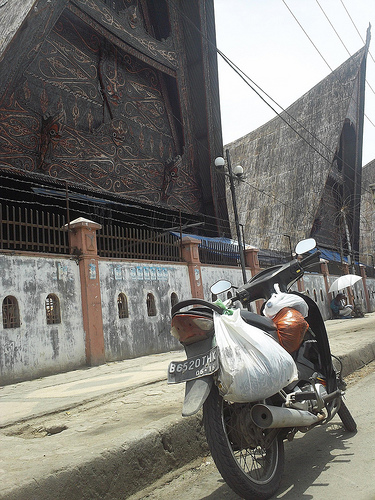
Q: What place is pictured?
A: It is a sidewalk.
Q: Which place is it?
A: It is a sidewalk.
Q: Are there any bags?
A: Yes, there is a bag.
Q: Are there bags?
A: Yes, there is a bag.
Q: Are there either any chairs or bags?
A: Yes, there is a bag.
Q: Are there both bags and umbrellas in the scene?
A: Yes, there are both a bag and an umbrella.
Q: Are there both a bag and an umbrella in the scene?
A: Yes, there are both a bag and an umbrella.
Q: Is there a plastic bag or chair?
A: Yes, there is a plastic bag.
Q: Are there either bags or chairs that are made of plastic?
A: Yes, the bag is made of plastic.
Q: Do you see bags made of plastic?
A: Yes, there is a bag that is made of plastic.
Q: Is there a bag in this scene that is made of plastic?
A: Yes, there is a bag that is made of plastic.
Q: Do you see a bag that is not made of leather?
A: Yes, there is a bag that is made of plastic.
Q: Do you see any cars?
A: No, there are no cars.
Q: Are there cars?
A: No, there are no cars.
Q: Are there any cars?
A: No, there are no cars.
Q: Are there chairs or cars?
A: No, there are no cars or chairs.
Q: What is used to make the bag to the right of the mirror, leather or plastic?
A: The bag is made of plastic.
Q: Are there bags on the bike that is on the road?
A: Yes, there is a bag on the bike.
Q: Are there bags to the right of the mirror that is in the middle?
A: Yes, there is a bag to the right of the mirror.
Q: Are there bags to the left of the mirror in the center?
A: No, the bag is to the right of the mirror.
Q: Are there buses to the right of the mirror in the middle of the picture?
A: No, there is a bag to the right of the mirror.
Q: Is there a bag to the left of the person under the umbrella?
A: Yes, there is a bag to the left of the person.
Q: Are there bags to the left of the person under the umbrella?
A: Yes, there is a bag to the left of the person.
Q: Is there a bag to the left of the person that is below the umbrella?
A: Yes, there is a bag to the left of the person.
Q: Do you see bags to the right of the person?
A: No, the bag is to the left of the person.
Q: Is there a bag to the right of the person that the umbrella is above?
A: No, the bag is to the left of the person.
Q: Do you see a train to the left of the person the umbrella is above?
A: No, there is a bag to the left of the person.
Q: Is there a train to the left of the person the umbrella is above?
A: No, there is a bag to the left of the person.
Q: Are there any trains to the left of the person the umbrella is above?
A: No, there is a bag to the left of the person.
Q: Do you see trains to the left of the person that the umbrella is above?
A: No, there is a bag to the left of the person.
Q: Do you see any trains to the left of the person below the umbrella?
A: No, there is a bag to the left of the person.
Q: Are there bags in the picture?
A: Yes, there is a bag.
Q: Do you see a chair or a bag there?
A: Yes, there is a bag.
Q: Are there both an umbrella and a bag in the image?
A: Yes, there are both a bag and an umbrella.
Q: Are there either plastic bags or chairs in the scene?
A: Yes, there is a plastic bag.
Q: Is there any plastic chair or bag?
A: Yes, there is a plastic bag.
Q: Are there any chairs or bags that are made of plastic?
A: Yes, the bag is made of plastic.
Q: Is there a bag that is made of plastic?
A: Yes, there is a bag that is made of plastic.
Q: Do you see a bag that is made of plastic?
A: Yes, there is a bag that is made of plastic.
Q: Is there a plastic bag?
A: Yes, there is a bag that is made of plastic.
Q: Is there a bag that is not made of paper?
A: Yes, there is a bag that is made of plastic.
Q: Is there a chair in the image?
A: No, there are no chairs.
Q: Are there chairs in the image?
A: No, there are no chairs.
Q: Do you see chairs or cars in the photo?
A: No, there are no chairs or cars.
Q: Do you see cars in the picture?
A: No, there are no cars.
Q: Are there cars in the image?
A: No, there are no cars.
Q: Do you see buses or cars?
A: No, there are no cars or buses.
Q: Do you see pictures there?
A: No, there are no pictures.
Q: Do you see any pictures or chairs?
A: No, there are no pictures or chairs.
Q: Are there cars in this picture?
A: No, there are no cars.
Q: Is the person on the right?
A: Yes, the person is on the right of the image.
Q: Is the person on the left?
A: No, the person is on the right of the image.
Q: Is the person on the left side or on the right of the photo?
A: The person is on the right of the image.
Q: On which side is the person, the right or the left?
A: The person is on the right of the image.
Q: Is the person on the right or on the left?
A: The person is on the right of the image.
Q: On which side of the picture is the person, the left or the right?
A: The person is on the right of the image.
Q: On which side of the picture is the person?
A: The person is on the right of the image.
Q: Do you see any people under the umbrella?
A: Yes, there is a person under the umbrella.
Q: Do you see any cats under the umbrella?
A: No, there is a person under the umbrella.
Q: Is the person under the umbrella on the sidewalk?
A: Yes, the person is under the umbrella.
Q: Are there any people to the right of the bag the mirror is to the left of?
A: Yes, there is a person to the right of the bag.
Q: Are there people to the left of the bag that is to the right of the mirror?
A: No, the person is to the right of the bag.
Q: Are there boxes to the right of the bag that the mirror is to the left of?
A: No, there is a person to the right of the bag.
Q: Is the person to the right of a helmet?
A: No, the person is to the right of a bag.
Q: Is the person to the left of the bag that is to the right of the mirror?
A: No, the person is to the right of the bag.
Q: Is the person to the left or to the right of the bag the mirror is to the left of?
A: The person is to the right of the bag.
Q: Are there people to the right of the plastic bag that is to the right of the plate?
A: Yes, there is a person to the right of the bag.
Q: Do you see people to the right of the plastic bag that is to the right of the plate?
A: Yes, there is a person to the right of the bag.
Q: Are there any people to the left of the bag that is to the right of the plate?
A: No, the person is to the right of the bag.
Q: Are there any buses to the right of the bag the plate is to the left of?
A: No, there is a person to the right of the bag.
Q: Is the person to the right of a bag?
A: Yes, the person is to the right of a bag.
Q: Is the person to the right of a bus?
A: No, the person is to the right of a bag.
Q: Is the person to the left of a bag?
A: No, the person is to the right of a bag.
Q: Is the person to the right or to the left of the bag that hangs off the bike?
A: The person is to the right of the bag.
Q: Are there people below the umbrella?
A: Yes, there is a person below the umbrella.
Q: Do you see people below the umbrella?
A: Yes, there is a person below the umbrella.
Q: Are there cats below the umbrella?
A: No, there is a person below the umbrella.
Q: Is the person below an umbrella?
A: Yes, the person is below an umbrella.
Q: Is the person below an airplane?
A: No, the person is below an umbrella.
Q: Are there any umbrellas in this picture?
A: Yes, there is an umbrella.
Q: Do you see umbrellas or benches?
A: Yes, there is an umbrella.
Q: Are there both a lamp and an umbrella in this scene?
A: Yes, there are both an umbrella and a lamp.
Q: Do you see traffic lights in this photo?
A: No, there are no traffic lights.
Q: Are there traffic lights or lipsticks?
A: No, there are no traffic lights or lipsticks.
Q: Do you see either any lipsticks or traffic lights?
A: No, there are no traffic lights or lipsticks.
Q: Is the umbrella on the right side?
A: Yes, the umbrella is on the right of the image.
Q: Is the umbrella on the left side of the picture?
A: No, the umbrella is on the right of the image.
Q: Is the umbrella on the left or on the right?
A: The umbrella is on the right of the image.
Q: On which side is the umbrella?
A: The umbrella is on the right of the image.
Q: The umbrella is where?
A: The umbrella is on the sidewalk.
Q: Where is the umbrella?
A: The umbrella is on the sidewalk.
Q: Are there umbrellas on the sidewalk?
A: Yes, there is an umbrella on the sidewalk.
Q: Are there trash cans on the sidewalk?
A: No, there is an umbrella on the sidewalk.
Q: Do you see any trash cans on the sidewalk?
A: No, there is an umbrella on the sidewalk.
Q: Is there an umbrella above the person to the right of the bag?
A: Yes, there is an umbrella above the person.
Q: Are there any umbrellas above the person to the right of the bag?
A: Yes, there is an umbrella above the person.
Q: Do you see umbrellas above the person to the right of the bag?
A: Yes, there is an umbrella above the person.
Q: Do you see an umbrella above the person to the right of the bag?
A: Yes, there is an umbrella above the person.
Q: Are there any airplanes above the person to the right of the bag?
A: No, there is an umbrella above the person.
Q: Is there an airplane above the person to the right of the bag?
A: No, there is an umbrella above the person.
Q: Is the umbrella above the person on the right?
A: Yes, the umbrella is above the person.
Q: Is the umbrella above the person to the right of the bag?
A: Yes, the umbrella is above the person.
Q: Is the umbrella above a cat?
A: No, the umbrella is above the person.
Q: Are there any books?
A: No, there are no books.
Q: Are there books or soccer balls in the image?
A: No, there are no books or soccer balls.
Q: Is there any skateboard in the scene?
A: No, there are no skateboards.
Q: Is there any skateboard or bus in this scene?
A: No, there are no skateboards or buses.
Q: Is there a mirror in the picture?
A: Yes, there is a mirror.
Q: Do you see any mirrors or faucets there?
A: Yes, there is a mirror.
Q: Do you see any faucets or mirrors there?
A: Yes, there is a mirror.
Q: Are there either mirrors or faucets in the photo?
A: Yes, there is a mirror.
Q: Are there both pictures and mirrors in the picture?
A: No, there is a mirror but no pictures.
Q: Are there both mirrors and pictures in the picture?
A: No, there is a mirror but no pictures.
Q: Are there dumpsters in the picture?
A: No, there are no dumpsters.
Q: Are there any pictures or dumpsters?
A: No, there are no dumpsters or pictures.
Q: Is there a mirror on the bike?
A: Yes, there is a mirror on the bike.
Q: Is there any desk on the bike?
A: No, there is a mirror on the bike.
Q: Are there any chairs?
A: No, there are no chairs.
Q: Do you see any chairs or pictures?
A: No, there are no chairs or pictures.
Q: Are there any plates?
A: Yes, there is a plate.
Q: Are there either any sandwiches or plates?
A: Yes, there is a plate.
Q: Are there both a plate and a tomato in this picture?
A: No, there is a plate but no tomatoes.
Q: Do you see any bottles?
A: No, there are no bottles.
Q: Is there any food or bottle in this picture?
A: No, there are no bottles or food.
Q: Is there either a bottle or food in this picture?
A: No, there are no bottles or food.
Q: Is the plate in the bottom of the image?
A: Yes, the plate is in the bottom of the image.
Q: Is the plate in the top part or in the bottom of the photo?
A: The plate is in the bottom of the image.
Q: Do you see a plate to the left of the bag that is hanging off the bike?
A: Yes, there is a plate to the left of the bag.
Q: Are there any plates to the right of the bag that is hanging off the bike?
A: No, the plate is to the left of the bag.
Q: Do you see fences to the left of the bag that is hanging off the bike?
A: No, there is a plate to the left of the bag.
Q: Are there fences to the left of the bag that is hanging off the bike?
A: No, there is a plate to the left of the bag.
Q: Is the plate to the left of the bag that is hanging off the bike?
A: Yes, the plate is to the left of the bag.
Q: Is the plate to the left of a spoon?
A: No, the plate is to the left of the bag.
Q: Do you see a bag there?
A: Yes, there is a bag.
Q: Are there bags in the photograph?
A: Yes, there is a bag.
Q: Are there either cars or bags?
A: Yes, there is a bag.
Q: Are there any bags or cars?
A: Yes, there is a bag.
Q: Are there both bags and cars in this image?
A: No, there is a bag but no cars.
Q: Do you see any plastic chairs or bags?
A: Yes, there is a plastic bag.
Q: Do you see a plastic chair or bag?
A: Yes, there is a plastic bag.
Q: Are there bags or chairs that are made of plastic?
A: Yes, the bag is made of plastic.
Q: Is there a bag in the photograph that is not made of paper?
A: Yes, there is a bag that is made of plastic.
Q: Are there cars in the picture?
A: No, there are no cars.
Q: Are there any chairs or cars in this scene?
A: No, there are no cars or chairs.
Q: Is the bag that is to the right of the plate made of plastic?
A: Yes, the bag is made of plastic.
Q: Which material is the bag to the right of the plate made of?
A: The bag is made of plastic.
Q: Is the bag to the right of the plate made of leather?
A: No, the bag is made of plastic.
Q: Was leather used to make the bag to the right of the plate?
A: No, the bag is made of plastic.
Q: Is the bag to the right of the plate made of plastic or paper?
A: The bag is made of plastic.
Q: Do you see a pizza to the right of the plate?
A: No, there is a bag to the right of the plate.